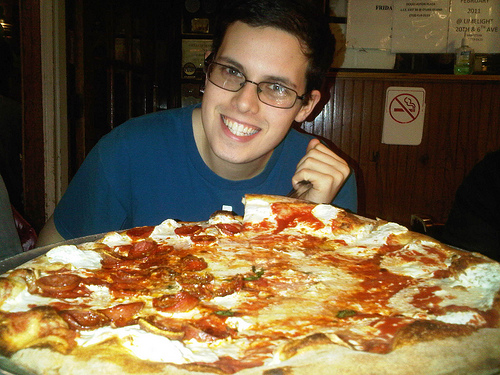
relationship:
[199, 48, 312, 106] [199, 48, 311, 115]
glasses of glasses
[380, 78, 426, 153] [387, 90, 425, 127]
sign for no smoking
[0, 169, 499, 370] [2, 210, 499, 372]
pizza on pan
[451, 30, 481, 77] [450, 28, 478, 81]
bottle of sanitizer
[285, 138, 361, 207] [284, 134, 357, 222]
hand holding spatula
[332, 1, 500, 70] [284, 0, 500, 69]
announcements on wall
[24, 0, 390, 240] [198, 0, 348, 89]
boy has hair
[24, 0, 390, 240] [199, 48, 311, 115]
boy wearing glasses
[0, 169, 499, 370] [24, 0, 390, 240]
pizza in front of boy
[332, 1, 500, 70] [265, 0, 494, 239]
announcements in back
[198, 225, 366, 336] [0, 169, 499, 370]
cheese on pizza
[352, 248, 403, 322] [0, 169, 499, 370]
sauce on pizza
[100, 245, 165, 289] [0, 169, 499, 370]
pepperoni on pizza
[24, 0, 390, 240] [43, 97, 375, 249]
boy has shirt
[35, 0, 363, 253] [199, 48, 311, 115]
boy wearing glasses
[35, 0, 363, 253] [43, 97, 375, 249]
boy wearing shirt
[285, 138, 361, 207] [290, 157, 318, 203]
hand holding utensil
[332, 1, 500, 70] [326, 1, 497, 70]
announcements on board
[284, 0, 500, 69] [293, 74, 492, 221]
wall has sign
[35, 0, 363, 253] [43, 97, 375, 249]
boy in shirt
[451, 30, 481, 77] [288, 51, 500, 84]
bottle on shelf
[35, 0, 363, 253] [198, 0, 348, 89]
boy has hair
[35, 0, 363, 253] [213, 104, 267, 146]
boy with smile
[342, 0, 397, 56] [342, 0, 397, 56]
paper of paper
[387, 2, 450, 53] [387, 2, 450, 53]
sheet of sheet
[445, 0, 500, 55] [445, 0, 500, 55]
sheet of sheet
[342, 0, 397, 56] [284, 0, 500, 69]
paper on wall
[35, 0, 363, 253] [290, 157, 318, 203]
boy holding utensil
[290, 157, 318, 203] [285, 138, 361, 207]
utensil in hand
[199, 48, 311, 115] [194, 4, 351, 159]
glasses on face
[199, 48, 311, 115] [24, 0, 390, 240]
glasses on boy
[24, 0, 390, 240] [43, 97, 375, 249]
boy in shirt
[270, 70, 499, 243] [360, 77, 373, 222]
wall has planks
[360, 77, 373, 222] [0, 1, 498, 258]
planks in background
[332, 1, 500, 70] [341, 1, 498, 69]
announcements in covers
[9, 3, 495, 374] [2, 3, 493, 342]
scene in restaurant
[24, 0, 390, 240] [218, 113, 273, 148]
boy has teeth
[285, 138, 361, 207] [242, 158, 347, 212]
hand holding spatula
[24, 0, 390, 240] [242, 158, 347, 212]
boy holding spatula